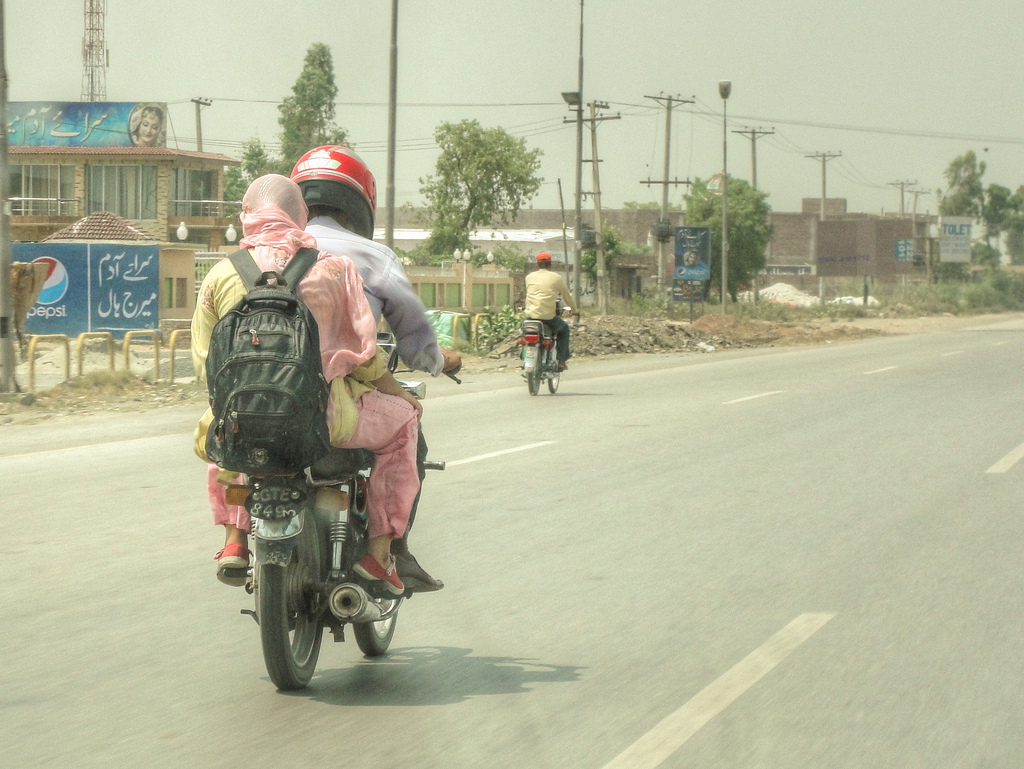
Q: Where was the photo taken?
A: In the street.